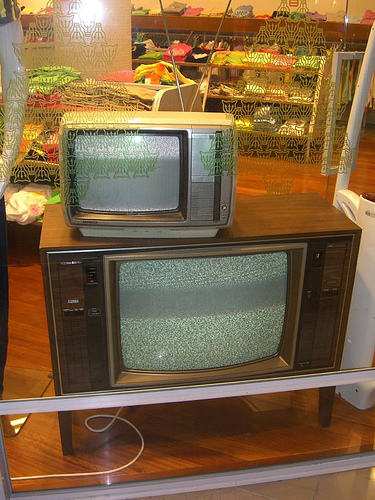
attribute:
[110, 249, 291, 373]
screen — grey and white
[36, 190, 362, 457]
tv — old, large, brown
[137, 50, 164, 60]
shirt — folded, green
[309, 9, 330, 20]
shirt — purple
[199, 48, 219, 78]
antena — metal, rabbit ear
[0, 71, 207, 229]
shelf — top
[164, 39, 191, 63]
tee shirt — pink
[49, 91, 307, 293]
tv — brown 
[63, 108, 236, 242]
tv — old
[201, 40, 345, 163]
shelf — brown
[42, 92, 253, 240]
television — large, screen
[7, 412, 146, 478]
cord — white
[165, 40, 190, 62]
shirt — folded, pink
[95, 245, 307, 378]
television — brown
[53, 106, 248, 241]
box tv — small, tan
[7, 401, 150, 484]
cord — white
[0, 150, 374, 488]
floor — wooden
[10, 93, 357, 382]
tv — in a store display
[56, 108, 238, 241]
television — silver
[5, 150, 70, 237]
shirt — black, tee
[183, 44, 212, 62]
folded shirt — black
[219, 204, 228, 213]
button — silver